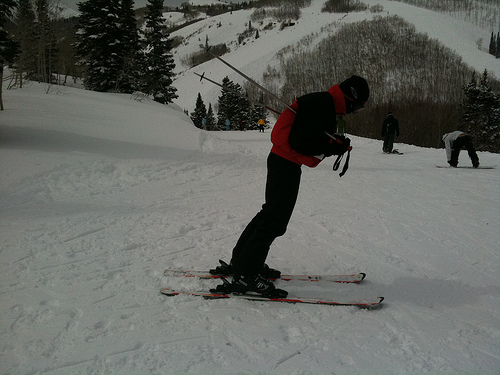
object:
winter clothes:
[271, 84, 347, 169]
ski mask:
[339, 75, 370, 114]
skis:
[160, 289, 384, 307]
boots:
[232, 273, 275, 295]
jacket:
[270, 84, 346, 167]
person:
[441, 130, 480, 167]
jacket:
[257, 119, 265, 125]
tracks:
[1, 131, 500, 374]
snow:
[1, 2, 500, 374]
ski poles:
[199, 44, 352, 151]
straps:
[339, 151, 350, 178]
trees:
[139, 1, 179, 105]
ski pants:
[231, 151, 301, 276]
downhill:
[1, 71, 500, 375]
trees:
[241, 14, 499, 148]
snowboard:
[436, 165, 494, 168]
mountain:
[31, 0, 500, 142]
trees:
[190, 92, 214, 129]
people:
[228, 76, 370, 297]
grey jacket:
[441, 130, 465, 161]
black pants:
[450, 134, 479, 168]